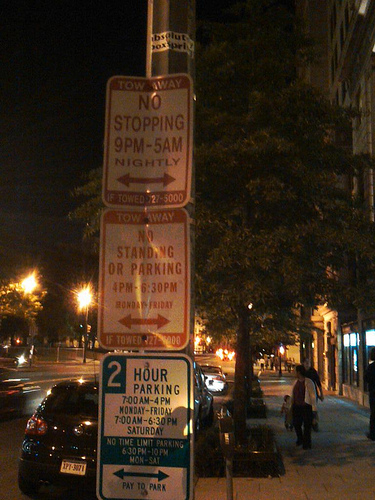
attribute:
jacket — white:
[287, 373, 330, 414]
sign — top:
[91, 68, 222, 178]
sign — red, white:
[103, 73, 191, 211]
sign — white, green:
[94, 353, 215, 497]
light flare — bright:
[77, 286, 97, 310]